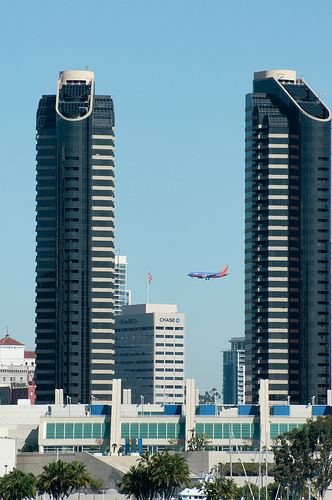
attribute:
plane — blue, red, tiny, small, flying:
[177, 263, 239, 291]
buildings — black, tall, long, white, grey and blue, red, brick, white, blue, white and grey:
[27, 46, 331, 401]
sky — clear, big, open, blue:
[0, 3, 329, 394]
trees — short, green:
[2, 427, 331, 499]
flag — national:
[136, 266, 167, 305]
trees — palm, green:
[3, 447, 252, 494]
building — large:
[254, 89, 322, 244]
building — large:
[30, 87, 136, 399]